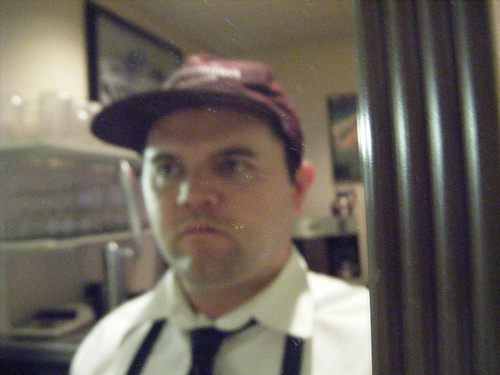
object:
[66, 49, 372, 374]
worker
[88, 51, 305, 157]
hat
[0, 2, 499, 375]
restaurant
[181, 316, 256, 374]
tie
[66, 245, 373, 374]
shirt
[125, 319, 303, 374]
apron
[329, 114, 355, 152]
train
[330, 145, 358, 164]
tracks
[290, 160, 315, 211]
ear